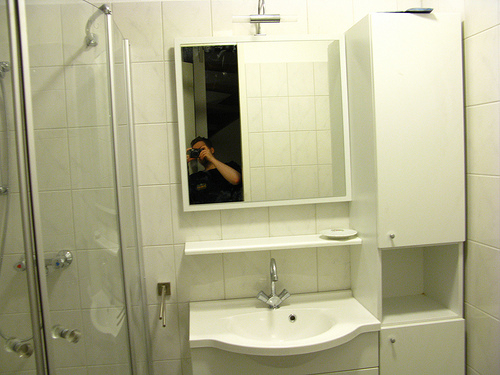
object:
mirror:
[174, 43, 347, 207]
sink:
[188, 304, 374, 352]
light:
[243, 12, 282, 35]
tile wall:
[131, 47, 166, 118]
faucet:
[257, 257, 291, 307]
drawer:
[189, 336, 382, 374]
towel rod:
[151, 279, 174, 325]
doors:
[19, 12, 117, 164]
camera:
[188, 146, 201, 158]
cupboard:
[346, 12, 466, 247]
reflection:
[203, 66, 242, 118]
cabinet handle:
[385, 233, 398, 239]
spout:
[272, 275, 282, 282]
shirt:
[189, 164, 244, 204]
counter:
[183, 229, 361, 256]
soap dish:
[312, 227, 362, 239]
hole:
[289, 314, 297, 323]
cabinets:
[379, 239, 467, 326]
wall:
[243, 60, 325, 193]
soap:
[318, 225, 358, 238]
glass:
[66, 50, 109, 102]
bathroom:
[0, 0, 499, 240]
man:
[185, 136, 240, 204]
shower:
[0, 0, 139, 375]